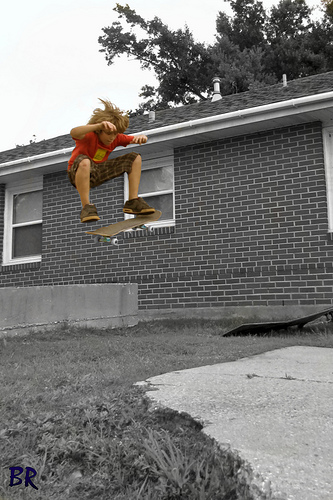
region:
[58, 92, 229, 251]
Boy jumping in the air.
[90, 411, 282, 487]
Grass on the ground.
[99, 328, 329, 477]
Cement by the grass.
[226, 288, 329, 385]
Ramp on the road.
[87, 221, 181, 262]
skateboard under the boy.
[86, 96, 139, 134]
Boy's hair flying in the air.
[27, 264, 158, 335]
Stone wall on the grass.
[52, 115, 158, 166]
Red shirt on the boy.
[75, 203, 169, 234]
Brown shoes on the skateboard.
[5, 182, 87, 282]
Window on the house/.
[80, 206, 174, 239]
skate board in the air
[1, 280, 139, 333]
cement wall in middle left of picture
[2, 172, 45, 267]
first window on the left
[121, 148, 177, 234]
window in center of picture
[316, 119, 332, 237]
window on right of picture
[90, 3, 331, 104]
tree in upper right of picture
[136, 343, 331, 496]
cement patch in lower right of picture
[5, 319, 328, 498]
grass in lower portion of picture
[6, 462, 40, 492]
"BR" in lower left corner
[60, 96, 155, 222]
boy on a skate board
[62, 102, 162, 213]
boy jumping a skate board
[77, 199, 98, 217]
right foot of boy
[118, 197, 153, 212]
left foot of boy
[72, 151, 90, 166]
right knee of boy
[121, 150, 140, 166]
left knee of boy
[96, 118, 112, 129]
right hand of boy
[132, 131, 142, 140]
left hand of boy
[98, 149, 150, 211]
left leg of boy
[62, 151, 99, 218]
right leg of boy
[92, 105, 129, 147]
head of boy on skate board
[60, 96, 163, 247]
Boy on skateboard.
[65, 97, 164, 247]
Boy in red shirt on skateboard.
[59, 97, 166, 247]
Boy doing trick on skateboard.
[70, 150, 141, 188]
Pants are brown.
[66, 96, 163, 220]
Boy has blond hair.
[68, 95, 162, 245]
Boy is flying on skateboard.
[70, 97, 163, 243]
Boy is in air on skateboard.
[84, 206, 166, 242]
Skateboard is in the air.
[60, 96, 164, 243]
Boy performing on skateboard.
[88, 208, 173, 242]
Skateboard is brown.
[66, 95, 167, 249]
a small boy is performing a skateboard trick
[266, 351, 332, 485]
concrete pavement with grass growing up in a crack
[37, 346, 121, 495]
a field of grass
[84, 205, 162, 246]
a brown skateboard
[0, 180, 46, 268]
window to a building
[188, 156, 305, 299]
the brick exterior of a building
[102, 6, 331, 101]
a large tree looms over a house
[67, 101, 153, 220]
a child wears a red shirt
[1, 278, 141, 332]
a miniature concrete wall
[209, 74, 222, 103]
a vent on top of a roof